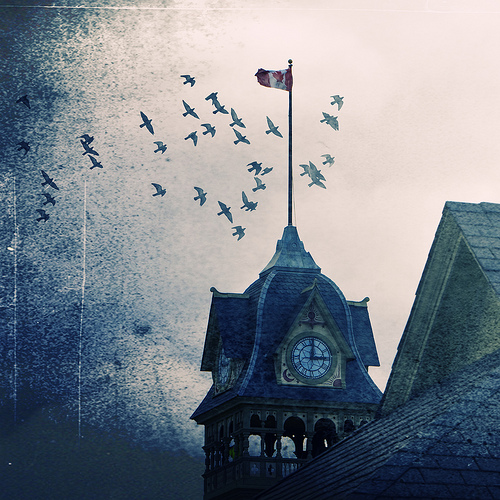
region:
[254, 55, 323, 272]
A flag pole on top of the building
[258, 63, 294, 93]
A Canadian flag flies in the air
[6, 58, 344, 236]
Birds fly behind the flag pole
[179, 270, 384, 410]
The cupola has two clock faces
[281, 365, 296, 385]
A half moon on the face of the clock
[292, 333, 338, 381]
The clock strikes three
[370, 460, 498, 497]
The roofing tiles are black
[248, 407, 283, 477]
An intricate archway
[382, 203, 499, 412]
The roof is triangular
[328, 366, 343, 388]
A sun is on the face of the clock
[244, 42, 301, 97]
Canadian flag at the top of the flag pole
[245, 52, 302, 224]
Flag pole on top of the building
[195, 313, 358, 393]
Big Clocks at the top of the tower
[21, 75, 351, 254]
Flock of birds flying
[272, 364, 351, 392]
Moon and Sun decoration on the clock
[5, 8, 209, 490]
Grainy affect in the sky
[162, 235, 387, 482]
Clock tower next to the building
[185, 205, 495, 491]
Two tall buidlings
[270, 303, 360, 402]
Gold and white clock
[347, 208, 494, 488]
Roof of the building on the right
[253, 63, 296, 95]
CANADIAN FLAG ON POLE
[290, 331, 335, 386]
CLOCK ON TOWER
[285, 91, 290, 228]
METAL FLAG POLE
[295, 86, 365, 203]
FLOCK OF BIRDS IN SKY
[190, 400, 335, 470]
BALCONY OF STEEPLE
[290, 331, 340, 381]
CLOCK SHOWS 3:00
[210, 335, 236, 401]
CLOCK ON OTHER SIDE OF TOWER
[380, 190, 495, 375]
PEAKED ROOF OF CHURCH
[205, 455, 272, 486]
BALCONY RAILING NEXT TO ROOF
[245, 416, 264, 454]
ARCHED WINDOWS IN BALCONY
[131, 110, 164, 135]
black bird in sky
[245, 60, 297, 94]
flag on pole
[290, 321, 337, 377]
clock on tower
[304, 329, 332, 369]
black hands on clock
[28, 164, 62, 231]
three black birds in sky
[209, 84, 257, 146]
birds in overcast sky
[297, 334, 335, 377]
white clock face on building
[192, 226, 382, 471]
clock on building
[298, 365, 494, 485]
shingle on rooftop of building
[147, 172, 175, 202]
black bird flying in sky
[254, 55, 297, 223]
Canadian flag on tall pole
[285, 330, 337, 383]
round clock with Roman numeral numbers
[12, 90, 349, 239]
several birds flying in the sky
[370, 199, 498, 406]
roof is shaped like a triangle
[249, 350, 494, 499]
roof covered in gray shingles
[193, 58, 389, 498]
old clock tower with flag on it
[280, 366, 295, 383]
moon decoration on bottom left of clock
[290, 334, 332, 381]
time on clock is three o'clock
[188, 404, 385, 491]
viewing area in clock tower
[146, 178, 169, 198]
bird is flapping it's wings